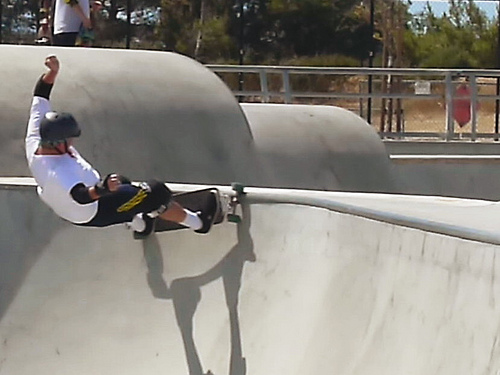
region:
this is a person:
[15, 42, 283, 298]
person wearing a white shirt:
[11, 82, 120, 242]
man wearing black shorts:
[60, 147, 180, 241]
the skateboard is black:
[118, 170, 259, 262]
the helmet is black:
[25, 105, 100, 160]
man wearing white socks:
[106, 205, 216, 255]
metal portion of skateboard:
[193, 185, 247, 222]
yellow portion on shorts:
[96, 175, 167, 222]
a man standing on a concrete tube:
[51, 1, 92, 46]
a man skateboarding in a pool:
[24, 56, 244, 241]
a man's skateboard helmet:
[40, 111, 80, 143]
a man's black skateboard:
[131, 181, 244, 236]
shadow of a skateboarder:
[141, 198, 255, 374]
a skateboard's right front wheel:
[225, 211, 242, 223]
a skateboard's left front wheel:
[230, 181, 244, 193]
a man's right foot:
[195, 191, 221, 233]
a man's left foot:
[132, 215, 153, 237]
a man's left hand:
[40, 56, 59, 76]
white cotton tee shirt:
[22, 95, 99, 225]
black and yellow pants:
[91, 184, 161, 228]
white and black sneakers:
[197, 189, 220, 236]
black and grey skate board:
[147, 189, 221, 231]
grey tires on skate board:
[225, 184, 246, 225]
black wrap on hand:
[94, 174, 112, 196]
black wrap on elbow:
[70, 182, 94, 207]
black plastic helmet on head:
[39, 112, 80, 144]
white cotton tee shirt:
[52, 1, 92, 37]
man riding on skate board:
[25, 55, 246, 243]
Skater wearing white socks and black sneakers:
[179, 189, 223, 236]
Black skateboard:
[130, 179, 251, 239]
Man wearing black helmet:
[35, 106, 85, 160]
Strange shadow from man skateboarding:
[125, 225, 303, 372]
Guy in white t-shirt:
[49, 0, 112, 42]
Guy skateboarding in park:
[25, 52, 257, 252]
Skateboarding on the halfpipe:
[16, 53, 231, 245]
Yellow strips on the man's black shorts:
[111, 182, 162, 218]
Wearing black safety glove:
[88, 174, 125, 209]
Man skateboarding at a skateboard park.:
[24, 55, 243, 243]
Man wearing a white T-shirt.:
[25, 96, 104, 226]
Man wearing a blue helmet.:
[39, 111, 82, 146]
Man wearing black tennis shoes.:
[130, 189, 220, 243]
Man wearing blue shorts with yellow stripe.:
[71, 174, 175, 229]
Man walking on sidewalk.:
[52, 2, 93, 47]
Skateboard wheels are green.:
[225, 182, 244, 225]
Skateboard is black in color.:
[132, 186, 219, 237]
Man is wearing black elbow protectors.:
[30, 74, 53, 103]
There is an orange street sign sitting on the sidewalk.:
[436, 80, 483, 129]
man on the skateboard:
[17, 79, 237, 256]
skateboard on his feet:
[127, 181, 243, 231]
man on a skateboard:
[14, 48, 257, 244]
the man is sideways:
[18, 45, 271, 266]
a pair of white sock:
[106, 205, 211, 232]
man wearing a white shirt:
[8, 90, 122, 241]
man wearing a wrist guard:
[85, 172, 121, 200]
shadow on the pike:
[129, 216, 279, 371]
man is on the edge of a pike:
[12, 57, 496, 285]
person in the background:
[37, 0, 114, 47]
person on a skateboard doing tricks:
[23, 68, 260, 251]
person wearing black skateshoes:
[185, 183, 225, 246]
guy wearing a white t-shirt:
[17, 92, 113, 242]